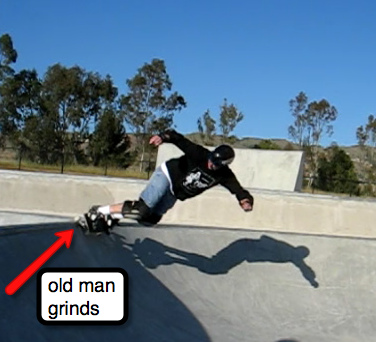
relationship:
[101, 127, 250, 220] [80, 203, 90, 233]
man on skateboard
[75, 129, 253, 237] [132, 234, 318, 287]
man has shadow